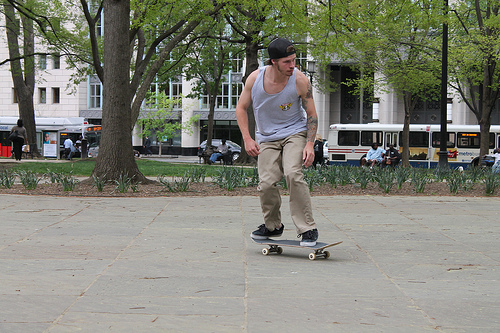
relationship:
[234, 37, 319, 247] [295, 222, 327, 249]
man wearing shoe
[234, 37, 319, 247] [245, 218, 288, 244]
man wearing shoe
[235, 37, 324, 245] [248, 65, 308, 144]
man in man's shirt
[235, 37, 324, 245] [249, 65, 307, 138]
man in muscle shirt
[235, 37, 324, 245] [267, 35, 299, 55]
man in cap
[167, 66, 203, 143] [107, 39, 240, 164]
column on building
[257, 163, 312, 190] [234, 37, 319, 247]
knees on man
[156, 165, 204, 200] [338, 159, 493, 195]
plant in garden area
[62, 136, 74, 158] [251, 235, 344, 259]
man on board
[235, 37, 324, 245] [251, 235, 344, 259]
man on board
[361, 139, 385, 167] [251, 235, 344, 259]
man on board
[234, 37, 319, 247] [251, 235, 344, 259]
man on board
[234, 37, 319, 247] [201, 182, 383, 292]
man on skateboard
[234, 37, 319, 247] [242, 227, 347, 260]
man on skateboard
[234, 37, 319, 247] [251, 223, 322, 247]
man wearing shoes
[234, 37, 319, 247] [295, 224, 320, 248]
man wearing shoe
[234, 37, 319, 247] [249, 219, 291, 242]
man wearing shoe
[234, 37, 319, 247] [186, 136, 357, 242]
man wearing pants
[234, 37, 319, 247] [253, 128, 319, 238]
man wearing pants